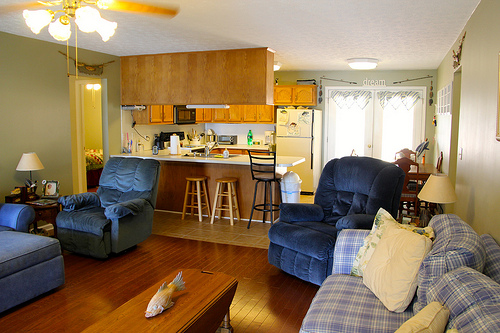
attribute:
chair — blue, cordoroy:
[270, 150, 397, 283]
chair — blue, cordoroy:
[56, 154, 158, 258]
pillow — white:
[368, 233, 427, 306]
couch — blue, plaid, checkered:
[307, 224, 498, 331]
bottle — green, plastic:
[247, 130, 254, 145]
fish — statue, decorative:
[146, 273, 188, 318]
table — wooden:
[83, 269, 243, 331]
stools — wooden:
[184, 176, 238, 222]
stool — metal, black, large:
[245, 147, 283, 229]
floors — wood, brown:
[0, 227, 312, 332]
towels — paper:
[169, 135, 181, 154]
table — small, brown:
[16, 199, 62, 235]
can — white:
[281, 173, 300, 203]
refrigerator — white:
[276, 110, 320, 192]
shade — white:
[15, 153, 43, 170]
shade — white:
[420, 175, 454, 205]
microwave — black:
[175, 105, 195, 123]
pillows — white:
[352, 209, 443, 312]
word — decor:
[362, 79, 388, 88]